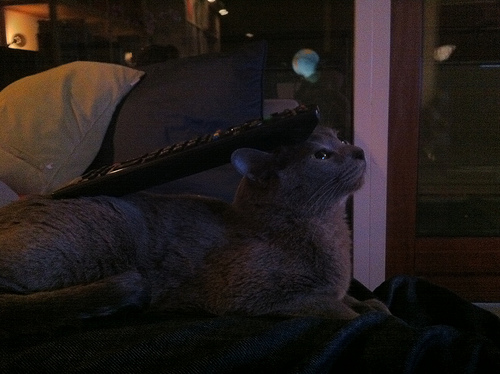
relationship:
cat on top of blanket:
[8, 119, 393, 329] [20, 286, 473, 371]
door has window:
[394, 6, 483, 283] [422, 16, 483, 230]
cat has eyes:
[0, 124, 395, 334] [312, 134, 351, 159]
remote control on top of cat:
[48, 104, 333, 202] [8, 119, 393, 329]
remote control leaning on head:
[48, 104, 333, 202] [223, 115, 362, 223]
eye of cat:
[317, 148, 334, 163] [8, 119, 393, 329]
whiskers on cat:
[292, 181, 370, 224] [72, 142, 422, 336]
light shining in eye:
[323, 150, 332, 161] [311, 146, 332, 164]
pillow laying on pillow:
[2, 61, 146, 204] [117, 40, 288, 163]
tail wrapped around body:
[10, 261, 146, 340] [4, 172, 284, 351]